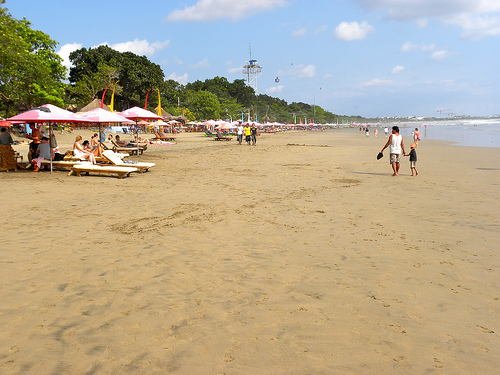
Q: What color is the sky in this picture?
A: Blue.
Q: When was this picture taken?
A: Daytime.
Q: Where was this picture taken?
A: The Beach.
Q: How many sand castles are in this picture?
A: Zero.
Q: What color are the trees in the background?
A: Green.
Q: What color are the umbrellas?
A: Red.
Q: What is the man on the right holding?
A: His Sandals.